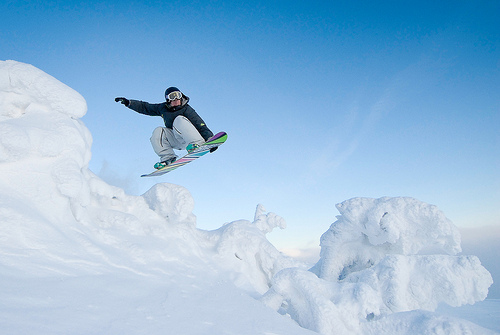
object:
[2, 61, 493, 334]
mountain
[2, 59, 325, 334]
slope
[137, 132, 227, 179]
snowboarder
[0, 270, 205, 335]
snow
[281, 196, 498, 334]
ground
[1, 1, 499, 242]
sky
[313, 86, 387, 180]
clouds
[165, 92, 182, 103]
goggles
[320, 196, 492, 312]
rocks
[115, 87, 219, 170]
man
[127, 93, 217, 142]
jacket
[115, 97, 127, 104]
gloves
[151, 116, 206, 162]
pants